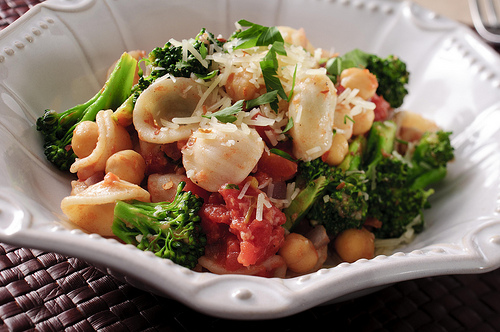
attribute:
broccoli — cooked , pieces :
[301, 150, 429, 207]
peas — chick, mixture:
[270, 230, 327, 270]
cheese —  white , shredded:
[128, 25, 418, 197]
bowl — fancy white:
[4, 1, 496, 313]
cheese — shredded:
[137, 22, 370, 152]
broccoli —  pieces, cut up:
[110, 190, 198, 263]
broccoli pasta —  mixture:
[288, 75, 451, 222]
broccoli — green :
[350, 142, 430, 222]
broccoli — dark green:
[309, 115, 464, 237]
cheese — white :
[189, 46, 329, 146]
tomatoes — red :
[202, 172, 287, 267]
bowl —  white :
[232, 264, 356, 323]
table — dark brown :
[6, 287, 134, 330]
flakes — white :
[247, 186, 270, 231]